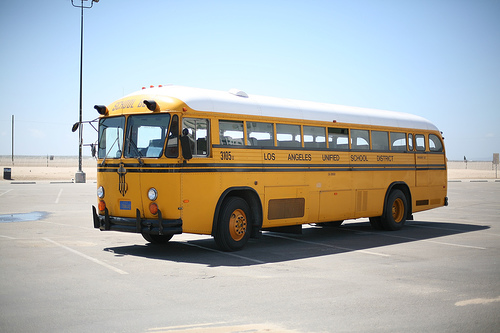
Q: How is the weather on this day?
A: It is clear.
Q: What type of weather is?
A: It is clear.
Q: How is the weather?
A: It is clear.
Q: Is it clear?
A: Yes, it is clear.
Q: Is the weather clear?
A: Yes, it is clear.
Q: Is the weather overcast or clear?
A: It is clear.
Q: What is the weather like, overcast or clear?
A: It is clear.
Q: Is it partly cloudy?
A: No, it is clear.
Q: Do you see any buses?
A: Yes, there is a bus.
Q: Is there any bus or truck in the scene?
A: Yes, there is a bus.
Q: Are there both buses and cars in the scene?
A: No, there is a bus but no cars.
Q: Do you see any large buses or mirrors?
A: Yes, there is a large bus.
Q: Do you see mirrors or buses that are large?
A: Yes, the bus is large.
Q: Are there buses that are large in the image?
A: Yes, there is a large bus.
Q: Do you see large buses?
A: Yes, there is a large bus.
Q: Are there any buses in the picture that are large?
A: Yes, there is a bus that is large.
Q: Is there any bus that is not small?
A: Yes, there is a large bus.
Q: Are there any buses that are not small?
A: Yes, there is a large bus.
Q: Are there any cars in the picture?
A: No, there are no cars.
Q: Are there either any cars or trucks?
A: No, there are no cars or trucks.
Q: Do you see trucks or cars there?
A: No, there are no cars or trucks.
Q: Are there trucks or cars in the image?
A: No, there are no cars or trucks.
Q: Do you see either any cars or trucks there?
A: No, there are no cars or trucks.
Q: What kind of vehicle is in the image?
A: The vehicle is a bus.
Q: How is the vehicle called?
A: The vehicle is a bus.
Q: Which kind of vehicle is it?
A: The vehicle is a bus.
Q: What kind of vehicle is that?
A: This is a bus.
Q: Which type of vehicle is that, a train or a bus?
A: This is a bus.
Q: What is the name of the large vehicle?
A: The vehicle is a bus.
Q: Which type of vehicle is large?
A: The vehicle is a bus.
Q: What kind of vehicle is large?
A: The vehicle is a bus.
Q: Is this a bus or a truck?
A: This is a bus.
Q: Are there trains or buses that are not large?
A: No, there is a bus but it is large.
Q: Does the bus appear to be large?
A: Yes, the bus is large.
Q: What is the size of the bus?
A: The bus is large.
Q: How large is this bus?
A: The bus is large.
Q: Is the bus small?
A: No, the bus is large.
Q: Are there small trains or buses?
A: No, there is a bus but it is large.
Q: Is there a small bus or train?
A: No, there is a bus but it is large.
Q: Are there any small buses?
A: No, there is a bus but it is large.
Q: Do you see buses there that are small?
A: No, there is a bus but it is large.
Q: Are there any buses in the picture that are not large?
A: No, there is a bus but it is large.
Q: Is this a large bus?
A: Yes, this is a large bus.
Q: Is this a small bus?
A: No, this is a large bus.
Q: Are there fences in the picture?
A: No, there are no fences.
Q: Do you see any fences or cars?
A: No, there are no fences or cars.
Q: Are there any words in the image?
A: Yes, there are words.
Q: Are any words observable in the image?
A: Yes, there are words.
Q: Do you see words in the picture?
A: Yes, there are words.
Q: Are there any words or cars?
A: Yes, there are words.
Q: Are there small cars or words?
A: Yes, there are small words.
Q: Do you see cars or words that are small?
A: Yes, the words are small.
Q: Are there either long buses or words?
A: Yes, there are long words.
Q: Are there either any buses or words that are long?
A: Yes, the words are long.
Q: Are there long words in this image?
A: Yes, there are long words.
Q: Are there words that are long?
A: Yes, there are words that are long.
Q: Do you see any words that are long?
A: Yes, there are words that are long.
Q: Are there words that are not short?
A: Yes, there are long words.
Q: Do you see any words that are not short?
A: Yes, there are long words.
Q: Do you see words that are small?
A: Yes, there are small words.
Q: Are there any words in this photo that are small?
A: Yes, there are words that are small.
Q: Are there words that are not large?
A: Yes, there are small words.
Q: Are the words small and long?
A: Yes, the words are small and long.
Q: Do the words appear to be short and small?
A: No, the words are small but long.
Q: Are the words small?
A: Yes, the words are small.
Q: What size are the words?
A: The words are small.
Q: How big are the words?
A: The words are small.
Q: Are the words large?
A: No, the words are small.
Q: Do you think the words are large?
A: No, the words are small.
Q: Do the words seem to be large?
A: No, the words are small.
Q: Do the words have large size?
A: No, the words are small.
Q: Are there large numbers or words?
A: No, there are words but they are small.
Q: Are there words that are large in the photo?
A: No, there are words but they are small.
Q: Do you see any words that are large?
A: No, there are words but they are small.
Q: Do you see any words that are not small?
A: No, there are words but they are small.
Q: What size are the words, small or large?
A: The words are small.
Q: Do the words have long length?
A: Yes, the words are long.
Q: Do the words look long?
A: Yes, the words are long.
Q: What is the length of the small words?
A: The words are long.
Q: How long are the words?
A: The words are long.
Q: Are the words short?
A: No, the words are long.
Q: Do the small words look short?
A: No, the words are long.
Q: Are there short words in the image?
A: No, there are words but they are long.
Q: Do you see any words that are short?
A: No, there are words but they are long.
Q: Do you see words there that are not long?
A: No, there are words but they are long.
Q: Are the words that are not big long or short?
A: The words are long.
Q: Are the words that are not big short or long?
A: The words are long.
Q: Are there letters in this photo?
A: Yes, there are letters.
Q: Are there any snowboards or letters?
A: Yes, there are letters.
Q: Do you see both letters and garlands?
A: No, there are letters but no garlands.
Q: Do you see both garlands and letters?
A: No, there are letters but no garlands.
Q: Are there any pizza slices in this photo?
A: No, there are no pizza slices.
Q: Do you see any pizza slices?
A: No, there are no pizza slices.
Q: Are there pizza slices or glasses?
A: No, there are no pizza slices or glasses.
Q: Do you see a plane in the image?
A: No, there are no airplanes.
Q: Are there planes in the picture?
A: No, there are no planes.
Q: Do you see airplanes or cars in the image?
A: No, there are no airplanes or cars.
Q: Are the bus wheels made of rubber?
A: Yes, the wheels are made of rubber.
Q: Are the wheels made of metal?
A: No, the wheels are made of rubber.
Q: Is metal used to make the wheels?
A: No, the wheels are made of rubber.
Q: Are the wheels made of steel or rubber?
A: The wheels are made of rubber.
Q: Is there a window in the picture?
A: Yes, there is a window.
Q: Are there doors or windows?
A: Yes, there is a window.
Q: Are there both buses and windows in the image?
A: Yes, there are both a window and a bus.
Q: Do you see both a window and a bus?
A: Yes, there are both a window and a bus.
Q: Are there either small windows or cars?
A: Yes, there is a small window.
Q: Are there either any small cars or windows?
A: Yes, there is a small window.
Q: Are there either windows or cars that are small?
A: Yes, the window is small.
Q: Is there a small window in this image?
A: Yes, there is a small window.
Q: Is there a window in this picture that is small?
A: Yes, there is a window that is small.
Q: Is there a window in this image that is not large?
A: Yes, there is a small window.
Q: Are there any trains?
A: No, there are no trains.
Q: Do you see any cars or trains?
A: No, there are no trains or cars.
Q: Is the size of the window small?
A: Yes, the window is small.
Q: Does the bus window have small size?
A: Yes, the window is small.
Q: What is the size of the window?
A: The window is small.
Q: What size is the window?
A: The window is small.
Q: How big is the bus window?
A: The window is small.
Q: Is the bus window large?
A: No, the window is small.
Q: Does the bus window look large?
A: No, the window is small.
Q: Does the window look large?
A: No, the window is small.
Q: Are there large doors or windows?
A: No, there is a window but it is small.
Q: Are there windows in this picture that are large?
A: No, there is a window but it is small.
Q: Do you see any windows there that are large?
A: No, there is a window but it is small.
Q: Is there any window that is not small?
A: No, there is a window but it is small.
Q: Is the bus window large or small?
A: The window is small.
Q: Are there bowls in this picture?
A: No, there are no bowls.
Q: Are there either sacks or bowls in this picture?
A: No, there are no bowls or sacks.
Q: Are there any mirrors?
A: Yes, there is a mirror.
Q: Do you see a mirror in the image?
A: Yes, there is a mirror.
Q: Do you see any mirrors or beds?
A: Yes, there is a mirror.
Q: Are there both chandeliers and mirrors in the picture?
A: No, there is a mirror but no chandeliers.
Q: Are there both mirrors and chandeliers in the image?
A: No, there is a mirror but no chandeliers.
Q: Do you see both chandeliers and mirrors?
A: No, there is a mirror but no chandeliers.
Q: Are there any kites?
A: No, there are no kites.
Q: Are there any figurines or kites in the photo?
A: No, there are no kites or figurines.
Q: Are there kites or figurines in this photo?
A: No, there are no kites or figurines.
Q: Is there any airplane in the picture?
A: No, there are no airplanes.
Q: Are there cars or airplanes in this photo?
A: No, there are no airplanes or cars.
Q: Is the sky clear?
A: Yes, the sky is clear.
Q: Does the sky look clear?
A: Yes, the sky is clear.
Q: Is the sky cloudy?
A: No, the sky is clear.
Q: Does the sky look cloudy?
A: No, the sky is clear.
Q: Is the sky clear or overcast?
A: The sky is clear.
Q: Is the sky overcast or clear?
A: The sky is clear.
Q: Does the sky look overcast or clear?
A: The sky is clear.